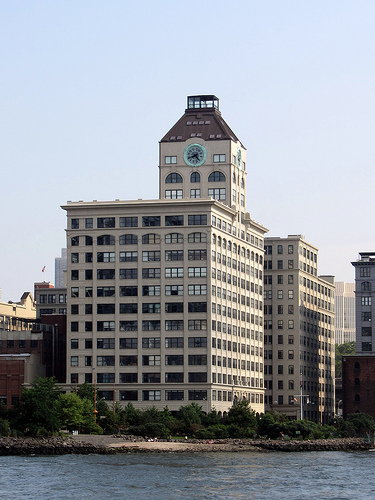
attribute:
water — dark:
[75, 451, 340, 482]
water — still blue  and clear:
[13, 479, 366, 500]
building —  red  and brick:
[4, 337, 40, 398]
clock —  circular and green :
[173, 135, 224, 169]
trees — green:
[1, 382, 373, 440]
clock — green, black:
[186, 143, 207, 170]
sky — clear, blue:
[1, 4, 373, 92]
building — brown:
[343, 357, 373, 415]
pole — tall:
[295, 386, 309, 420]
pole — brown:
[92, 366, 97, 431]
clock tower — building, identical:
[61, 92, 268, 428]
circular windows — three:
[162, 169, 228, 190]